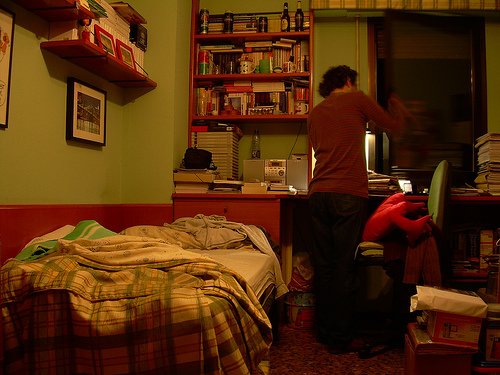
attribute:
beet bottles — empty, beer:
[193, 2, 310, 34]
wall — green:
[28, 89, 170, 180]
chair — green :
[351, 148, 465, 340]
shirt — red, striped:
[308, 94, 388, 201]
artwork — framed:
[52, 73, 114, 150]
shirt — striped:
[300, 93, 412, 203]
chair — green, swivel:
[366, 157, 461, 299]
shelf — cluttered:
[183, 12, 314, 120]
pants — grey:
[150, 196, 264, 295]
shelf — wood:
[40, 34, 158, 104]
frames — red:
[93, 25, 136, 70]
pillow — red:
[372, 176, 430, 266]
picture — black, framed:
[59, 77, 114, 153]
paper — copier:
[412, 283, 486, 318]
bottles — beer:
[278, 2, 308, 32]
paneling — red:
[0, 201, 173, 266]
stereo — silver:
[238, 154, 313, 191]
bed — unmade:
[0, 215, 282, 373]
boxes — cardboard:
[412, 283, 486, 357]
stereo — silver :
[260, 158, 289, 193]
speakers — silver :
[238, 150, 312, 196]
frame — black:
[53, 77, 139, 165]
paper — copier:
[404, 281, 490, 321]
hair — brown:
[307, 40, 384, 103]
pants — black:
[274, 158, 395, 328]